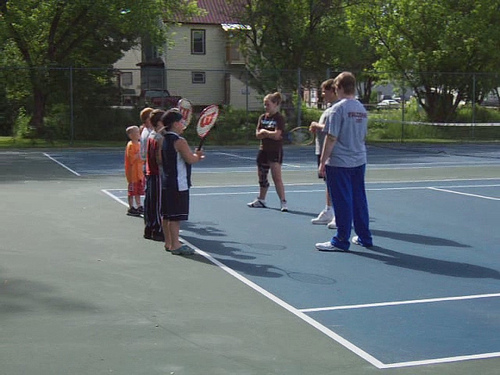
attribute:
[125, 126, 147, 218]
boy — small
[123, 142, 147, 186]
shirt — orange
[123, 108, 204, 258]
boys — a group of four, learning tennis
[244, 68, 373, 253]
adults — a group of three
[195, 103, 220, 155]
racquet — wilson brand, red, black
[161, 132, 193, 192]
tank top — blue, white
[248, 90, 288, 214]
woman — young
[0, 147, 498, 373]
tennis court — blue, green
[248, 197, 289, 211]
tennis shoes — white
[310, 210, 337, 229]
tennis shoes — white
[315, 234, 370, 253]
tennis shoes — white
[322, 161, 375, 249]
pants — blue, blue in color, long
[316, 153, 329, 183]
shorts — blue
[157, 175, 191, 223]
shorts — blue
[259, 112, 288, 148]
t-shirt — brown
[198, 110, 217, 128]
w — red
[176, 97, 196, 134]
racquet — wilson brand, red, black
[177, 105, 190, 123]
w — red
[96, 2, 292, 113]
house — in the background, yellow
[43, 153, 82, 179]
line — white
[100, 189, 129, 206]
line — white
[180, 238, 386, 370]
line — white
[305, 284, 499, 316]
line — white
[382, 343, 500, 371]
line — white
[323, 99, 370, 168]
t-shirt — gray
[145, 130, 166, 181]
shirt — red